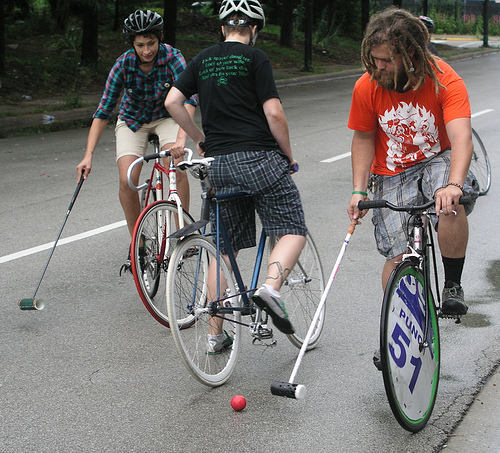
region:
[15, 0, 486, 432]
people playing a game of Hardcourt Bike Polo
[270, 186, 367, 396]
man holding a black and white mallet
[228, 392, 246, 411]
a red street hockey ball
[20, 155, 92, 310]
woman holding a green mallet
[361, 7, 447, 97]
man's brown hair is in dreadlocks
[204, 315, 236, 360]
player's foot is touching the ground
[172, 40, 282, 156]
player's black shirt has green writing on the back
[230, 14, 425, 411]
player is staring down at street hockey ball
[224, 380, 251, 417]
red ball on the pavement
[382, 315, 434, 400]
sign in the spokes of the tire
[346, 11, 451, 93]
man has dreads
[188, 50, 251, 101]
green writing on the back of the shirt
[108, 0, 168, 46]
woman is wearing a bike helmet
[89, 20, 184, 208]
woman is riding a bike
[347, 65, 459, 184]
man is wearing an orange shirt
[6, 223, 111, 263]
white line painted in the street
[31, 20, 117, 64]
trees across the street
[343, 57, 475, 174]
orange cotton tee shirt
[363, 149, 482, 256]
grey and black plaid shorts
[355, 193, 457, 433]
green and black bike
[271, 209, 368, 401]
white wooden polo stick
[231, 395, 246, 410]
red ball on street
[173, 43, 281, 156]
black cotton tee shirt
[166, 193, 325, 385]
blue and white bike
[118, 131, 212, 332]
red and white bike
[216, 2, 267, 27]
black and white helmet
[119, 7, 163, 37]
black helmet on head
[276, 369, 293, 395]
part of a stick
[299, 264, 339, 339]
part of a handle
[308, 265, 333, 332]
part of a handle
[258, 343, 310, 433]
part of a stick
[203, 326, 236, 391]
part of a wheel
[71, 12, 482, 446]
people riding the bikes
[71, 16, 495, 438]
people riding the bikes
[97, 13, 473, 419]
people riding the bikes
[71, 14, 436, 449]
people riding the bikes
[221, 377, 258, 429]
red ball on the ground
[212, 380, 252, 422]
red ball on the ground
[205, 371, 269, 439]
red ball on the ground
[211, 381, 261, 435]
red ball on the ground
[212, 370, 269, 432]
red ball on the ground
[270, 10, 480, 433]
man on a bicycle playing pogo